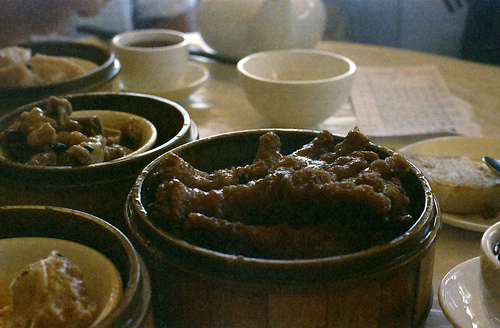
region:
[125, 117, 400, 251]
the food is in wooden bowl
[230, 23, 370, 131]
the bowl is white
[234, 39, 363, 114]
this is a bowl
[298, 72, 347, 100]
the bowl is white in color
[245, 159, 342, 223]
this is a beef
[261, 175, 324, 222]
the beef is brown in color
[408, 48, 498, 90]
this is the table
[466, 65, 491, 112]
the table is white in color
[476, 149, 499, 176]
this is a spoon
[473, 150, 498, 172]
the spoon is metalic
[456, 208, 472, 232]
this is a plate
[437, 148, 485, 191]
this is a cake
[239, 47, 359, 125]
a small white ceramic bowl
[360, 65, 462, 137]
a white napkin on the table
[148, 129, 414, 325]
a wooden bowl with teryaki chicken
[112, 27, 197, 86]
a cup of black coffee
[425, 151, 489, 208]
a yellow pastry on a white saucer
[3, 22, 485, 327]
a delicious resturant meal on a table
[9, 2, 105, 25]
a hand reaching out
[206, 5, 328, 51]
white ceramic pitcher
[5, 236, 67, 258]
a white bowl inside a wooden holder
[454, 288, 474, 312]
light reflecting on the saucer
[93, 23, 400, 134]
two cups in table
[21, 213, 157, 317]
a part of the food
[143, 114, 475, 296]
a delicious fry in box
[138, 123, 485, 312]
a hot looking food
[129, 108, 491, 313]
a highly roasted food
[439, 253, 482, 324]
a part of the plate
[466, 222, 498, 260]
a part of the cup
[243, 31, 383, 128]
a white empty cup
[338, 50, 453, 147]
a white paper in table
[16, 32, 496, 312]
a large table with food